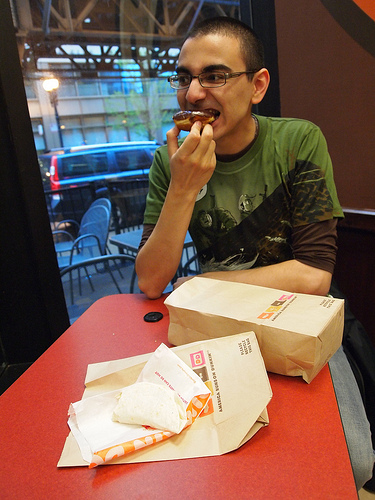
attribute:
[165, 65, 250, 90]
eyeglasses — silver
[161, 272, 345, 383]
bag — brown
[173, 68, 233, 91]
pair of — black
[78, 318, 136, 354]
table — orange, red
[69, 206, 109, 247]
metal chairs — grey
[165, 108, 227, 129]
donut — chocolate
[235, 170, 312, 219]
boys shirt — green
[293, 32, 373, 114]
wall — brown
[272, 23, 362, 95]
wall — brown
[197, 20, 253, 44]
hair — short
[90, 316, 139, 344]
table — orange, red, small, rectangular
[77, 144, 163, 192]
suv — blue, parked